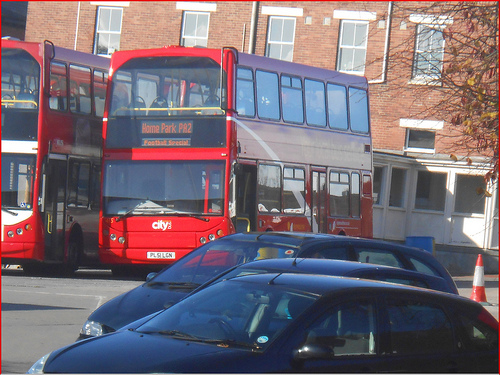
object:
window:
[109, 56, 226, 119]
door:
[42, 153, 68, 265]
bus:
[2, 34, 111, 278]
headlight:
[110, 232, 118, 242]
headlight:
[207, 232, 217, 242]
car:
[75, 229, 458, 340]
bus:
[93, 46, 372, 280]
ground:
[0, 270, 500, 375]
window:
[232, 63, 258, 116]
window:
[256, 69, 282, 121]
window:
[278, 72, 306, 126]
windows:
[302, 76, 328, 129]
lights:
[117, 236, 129, 245]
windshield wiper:
[114, 199, 146, 223]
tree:
[351, 0, 500, 198]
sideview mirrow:
[294, 344, 336, 365]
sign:
[135, 122, 194, 147]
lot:
[0, 265, 496, 373]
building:
[20, 0, 498, 272]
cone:
[469, 252, 492, 307]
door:
[234, 155, 264, 237]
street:
[0, 271, 500, 375]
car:
[27, 257, 500, 375]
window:
[402, 126, 437, 155]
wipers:
[172, 335, 262, 351]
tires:
[65, 229, 83, 275]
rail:
[112, 106, 223, 114]